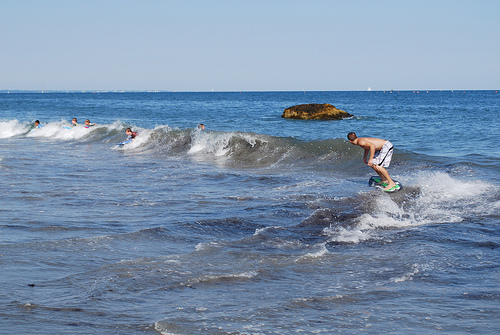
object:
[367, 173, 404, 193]
surf board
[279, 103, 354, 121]
island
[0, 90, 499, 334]
sea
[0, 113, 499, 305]
waves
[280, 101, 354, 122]
rock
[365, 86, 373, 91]
boats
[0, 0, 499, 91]
sky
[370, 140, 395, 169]
shorts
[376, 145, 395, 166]
stripe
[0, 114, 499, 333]
foam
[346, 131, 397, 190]
man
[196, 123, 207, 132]
people